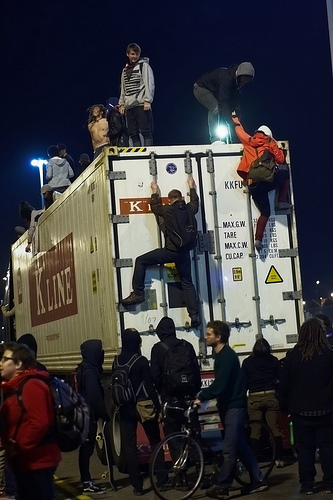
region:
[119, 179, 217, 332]
a person on a truck.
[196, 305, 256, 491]
a person standing behind a truck.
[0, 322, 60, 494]
a person in a red jacket.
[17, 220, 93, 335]
a red company logo.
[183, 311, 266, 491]
a man holding a bike.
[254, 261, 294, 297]
a yellow hazard label.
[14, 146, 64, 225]
a parking lot light.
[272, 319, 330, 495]
a person standing behind a truck.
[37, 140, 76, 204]
a person standing on a truck.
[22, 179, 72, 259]
a leg hanging off the side of a truck.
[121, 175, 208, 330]
man climbing back of truck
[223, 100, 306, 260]
person in orange jacket climbing truck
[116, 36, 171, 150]
man standing on top of truck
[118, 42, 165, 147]
man with short hair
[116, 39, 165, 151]
man wearing black and gray jacket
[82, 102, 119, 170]
man with long hair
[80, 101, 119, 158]
man without shirt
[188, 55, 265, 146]
man in black and gray hooded jacket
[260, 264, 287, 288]
yellow and black triangular sticker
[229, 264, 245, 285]
yellow and black rectangular sticker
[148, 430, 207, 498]
bicycle tire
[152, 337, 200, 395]
black backpack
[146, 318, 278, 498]
man wearing jeans holding bicycle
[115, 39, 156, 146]
boy in grey shirt standing on top of truck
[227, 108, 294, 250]
girl in orange jacket climbing onto truck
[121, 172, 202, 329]
young man climbing up back of truck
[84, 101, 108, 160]
shirtless man standing on top of truck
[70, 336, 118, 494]
person in dark jacket holding skateboard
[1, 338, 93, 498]
woman in red jacket wearing backpack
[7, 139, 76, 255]
group of people on top of truck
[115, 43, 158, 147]
person on top of semi truck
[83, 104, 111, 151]
person on top of semi truck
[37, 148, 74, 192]
person on top of semi truck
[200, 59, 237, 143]
person on top of semi truck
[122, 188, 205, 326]
person climbing on semi truck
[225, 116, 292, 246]
person climbing on semi truck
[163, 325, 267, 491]
person with black shirt on bicycle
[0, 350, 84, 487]
person with book bag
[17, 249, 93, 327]
logo on side of truck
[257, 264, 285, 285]
warning side on back of truck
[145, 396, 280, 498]
THE MAN IS PUSHING A BIKE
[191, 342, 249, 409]
THE MAN IS WEARING A GREEN SWEATSHIRT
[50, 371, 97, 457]
THE MAN IS WEARING A BACKPACK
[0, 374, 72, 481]
THE MAN IS WEARING A RED JACKET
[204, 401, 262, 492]
THE MAN IS WEARING JEANS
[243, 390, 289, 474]
THE GIRL IS WEARING BROWN PANTS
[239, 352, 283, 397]
THE GIRL IS WEARING A BLUE JACKET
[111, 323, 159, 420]
THE BOY IS WEARING A BLUE HOODY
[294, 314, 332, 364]
THE MAN HAS DREADLOCKS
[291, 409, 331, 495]
THE MAN HAS BLACK PANTS